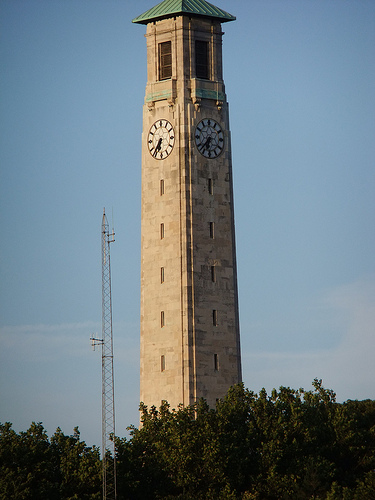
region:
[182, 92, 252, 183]
Clock on the tower.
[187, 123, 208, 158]
hands on the clock.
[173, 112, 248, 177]
Roman numerals on the clock.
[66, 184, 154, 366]
Wire tower by the tower.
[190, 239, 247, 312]
Windows on the tower.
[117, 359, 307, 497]
Tree in front of the tower.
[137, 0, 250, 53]
Roof on the tower.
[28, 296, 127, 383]
Clouds in the sky.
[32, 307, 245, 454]
Blue sky behind the tower.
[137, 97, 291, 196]
Two clocks on the tower.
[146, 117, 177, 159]
clock on large tower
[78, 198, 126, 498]
tall metal antenna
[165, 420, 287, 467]
trees with green leaves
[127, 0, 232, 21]
green metal roof on top of structure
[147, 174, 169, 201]
window on side of structure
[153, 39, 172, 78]
three pane window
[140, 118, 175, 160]
star in center of clock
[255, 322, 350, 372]
blue sky with clouds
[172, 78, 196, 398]
corner of tall structure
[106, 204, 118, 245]
antenna on antenna mast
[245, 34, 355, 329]
a clear blue sky overhead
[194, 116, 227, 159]
a black and white face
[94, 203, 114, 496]
a metal cell tower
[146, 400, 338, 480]
tall dark green trees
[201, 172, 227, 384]
rectangular windows in a building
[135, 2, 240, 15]
a green ridged roof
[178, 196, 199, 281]
tan and white bricks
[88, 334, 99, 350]
a metal support on the tower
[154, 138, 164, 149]
black hands on clock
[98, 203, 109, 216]
a point on top of the cell tower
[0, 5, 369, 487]
a big tower behind some trees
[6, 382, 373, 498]
trees in front a tower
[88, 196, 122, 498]
a metal pole in front a tower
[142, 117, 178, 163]
a white clock on side the tower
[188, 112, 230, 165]
a white clock on side the tower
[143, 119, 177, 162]
clock is white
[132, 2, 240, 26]
roof of tower is green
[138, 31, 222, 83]
windows under the roof of tower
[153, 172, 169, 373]
narrow windows below a clock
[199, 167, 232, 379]
narrow windows below a clock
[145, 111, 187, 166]
clock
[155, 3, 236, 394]
brown tower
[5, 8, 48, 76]
white clouds against blue sky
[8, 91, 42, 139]
white clouds against blue sky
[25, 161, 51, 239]
white clouds against blue sky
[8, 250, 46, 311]
white clouds against blue sky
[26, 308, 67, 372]
white clouds against blue sky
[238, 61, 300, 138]
white clouds against blue sky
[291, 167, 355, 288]
white clouds against blue sky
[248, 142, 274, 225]
white clouds against blue sky